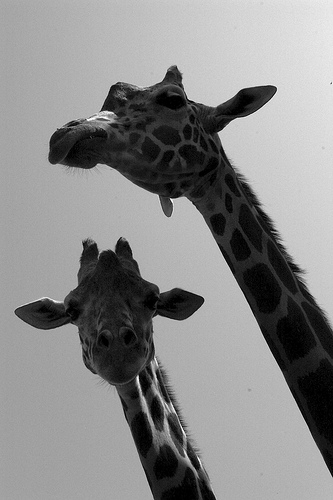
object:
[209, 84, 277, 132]
ear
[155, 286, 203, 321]
ear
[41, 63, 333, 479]
animal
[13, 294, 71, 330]
ear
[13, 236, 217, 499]
animal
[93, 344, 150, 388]
mouth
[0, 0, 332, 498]
photo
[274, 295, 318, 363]
spot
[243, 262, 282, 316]
spot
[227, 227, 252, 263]
spot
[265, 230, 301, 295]
spot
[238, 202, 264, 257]
spot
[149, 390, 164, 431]
spot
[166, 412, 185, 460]
spot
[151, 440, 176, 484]
spot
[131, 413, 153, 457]
spot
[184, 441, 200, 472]
spot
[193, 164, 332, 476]
neck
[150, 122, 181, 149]
black spots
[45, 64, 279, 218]
head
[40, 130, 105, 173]
mouth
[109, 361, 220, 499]
neck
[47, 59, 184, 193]
face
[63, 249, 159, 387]
face